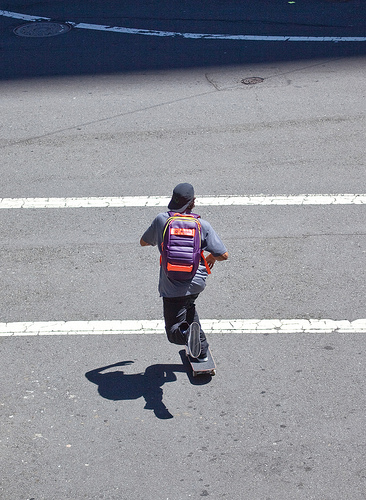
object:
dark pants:
[161, 294, 209, 357]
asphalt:
[1, 0, 364, 498]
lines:
[0, 11, 364, 42]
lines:
[0, 318, 366, 337]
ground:
[325, 101, 343, 114]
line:
[0, 192, 366, 210]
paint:
[262, 194, 366, 204]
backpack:
[161, 211, 201, 282]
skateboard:
[185, 344, 217, 377]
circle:
[13, 20, 71, 39]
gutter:
[203, 69, 220, 91]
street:
[3, 56, 362, 496]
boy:
[140, 182, 229, 363]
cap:
[167, 182, 194, 213]